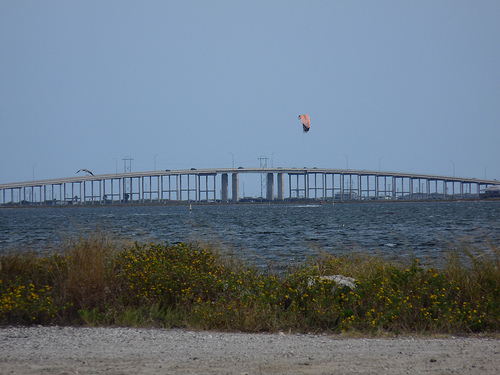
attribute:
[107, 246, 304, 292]
flowers — yellow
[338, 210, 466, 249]
water — calm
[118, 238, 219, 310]
flowers — yellow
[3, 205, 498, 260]
ocean — rippled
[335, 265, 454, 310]
flowers — yellow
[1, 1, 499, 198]
sky — blue, clear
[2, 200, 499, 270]
water — ocean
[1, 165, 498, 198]
bridge — long, above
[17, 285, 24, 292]
flower — yellow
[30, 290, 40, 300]
flower — yellow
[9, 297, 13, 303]
flower — yellow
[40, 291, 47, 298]
flower — yellow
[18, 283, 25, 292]
flower — yellow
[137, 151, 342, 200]
bridge — large